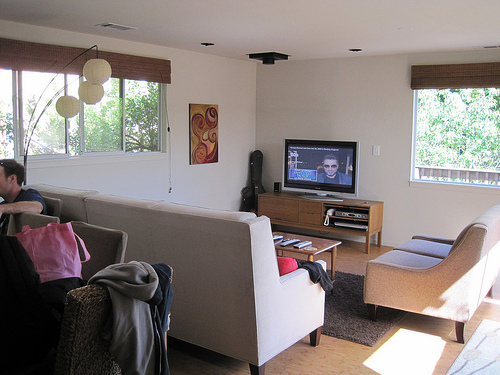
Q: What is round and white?
A: Light covers.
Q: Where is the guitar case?
A: Corner.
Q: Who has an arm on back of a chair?
A: Man on left.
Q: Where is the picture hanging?
A: Left of television.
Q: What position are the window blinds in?
A: Up.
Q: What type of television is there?
A: Flat screen.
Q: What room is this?
A: Living room.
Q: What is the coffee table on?
A: Rug.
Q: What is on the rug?
A: Coffee table and loveseat.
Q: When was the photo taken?
A: Daytime.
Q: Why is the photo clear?
A: Its during the day.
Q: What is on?
A: The tv.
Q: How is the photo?
A: Clear.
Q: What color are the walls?
A: White.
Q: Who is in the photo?
A: A man.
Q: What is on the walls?
A: A picture.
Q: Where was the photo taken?
A: In the living room.